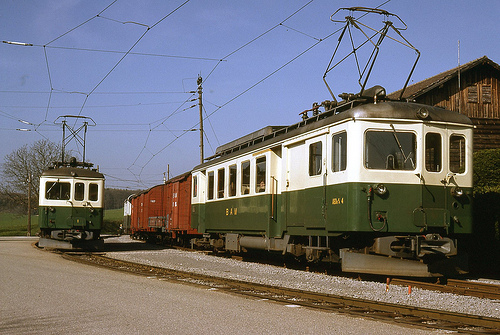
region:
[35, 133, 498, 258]
two green and white train cars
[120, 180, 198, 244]
red train car on tracks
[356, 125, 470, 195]
front windows of foreground train car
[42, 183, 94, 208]
front windows of background train car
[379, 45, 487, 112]
roof of building behind trains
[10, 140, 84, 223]
tree beside green and white train car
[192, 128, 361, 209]
side windows on green and white train car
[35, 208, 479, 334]
two sets of train tracks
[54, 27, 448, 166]
utility poles behind train cars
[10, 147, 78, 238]
tree beside train car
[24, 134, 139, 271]
Train riding down the track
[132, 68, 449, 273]
Train sitting on the track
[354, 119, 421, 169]
Front window on the train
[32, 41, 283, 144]
Power lines over the train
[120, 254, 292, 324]
The track is rusted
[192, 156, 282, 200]
Windows on the side of the train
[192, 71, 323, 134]
The sky is blue with no clouds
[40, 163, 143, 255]
The train is white and green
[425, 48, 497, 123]
Building sitting beside the track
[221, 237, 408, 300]
Metal underneath the train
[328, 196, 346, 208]
serial number on the trolley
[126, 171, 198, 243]
red trolley car that's different by colored red freight cars for transporting goods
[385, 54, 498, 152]
large weathered wooden building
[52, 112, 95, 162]
electrical conductor that powers the trolleys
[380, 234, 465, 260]
large metal connector used for attaching cars together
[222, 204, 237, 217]
name of the train/trolley company in stenciled yellow black l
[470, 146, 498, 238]
large green full bush or shrub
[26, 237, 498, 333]
tracks on which the trolleys and trains to run from place to place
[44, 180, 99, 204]
windshield on the front of the trolley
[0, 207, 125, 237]
grassy hill and field behind all these palf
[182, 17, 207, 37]
this is the sky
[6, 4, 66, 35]
the sky is blue in color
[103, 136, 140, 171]
the sky has some clouds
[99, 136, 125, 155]
the clouds are white in color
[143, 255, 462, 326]
these are railway lines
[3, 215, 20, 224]
this is the grass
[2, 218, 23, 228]
the grass is green in color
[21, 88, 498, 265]
these are some trains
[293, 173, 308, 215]
the train is white and green in color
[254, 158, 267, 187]
this is a window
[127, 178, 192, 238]
red box cars on a train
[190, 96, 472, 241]
green and white passenger car on the right track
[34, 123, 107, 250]
green and white passenger car on the left track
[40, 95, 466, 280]
two trains on separate tracks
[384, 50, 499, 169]
brown wooden building behind the train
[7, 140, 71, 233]
tree behind the left train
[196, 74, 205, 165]
pwoer pole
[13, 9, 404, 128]
electrical lines above the train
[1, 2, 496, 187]
clear blue sky above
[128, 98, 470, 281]
green passenger car hooked to box cars